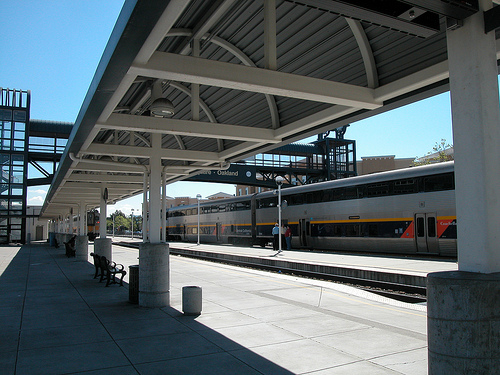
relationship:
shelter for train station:
[35, 0, 481, 227] [2, 2, 496, 370]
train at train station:
[142, 148, 469, 264] [2, 2, 496, 370]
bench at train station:
[86, 251, 135, 290] [2, 2, 496, 370]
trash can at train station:
[124, 261, 146, 306] [2, 2, 496, 370]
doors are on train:
[410, 208, 439, 257] [142, 148, 469, 264]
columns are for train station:
[50, 97, 177, 319] [2, 2, 496, 370]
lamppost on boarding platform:
[269, 168, 293, 259] [78, 233, 438, 355]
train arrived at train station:
[142, 148, 469, 264] [2, 2, 496, 370]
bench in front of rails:
[86, 251, 135, 290] [119, 236, 428, 313]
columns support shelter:
[50, 97, 177, 319] [35, 0, 481, 227]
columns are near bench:
[50, 97, 177, 319] [86, 251, 135, 290]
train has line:
[142, 148, 469, 264] [309, 214, 414, 230]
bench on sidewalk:
[86, 251, 135, 290] [14, 240, 209, 368]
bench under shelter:
[86, 251, 135, 290] [35, 0, 481, 227]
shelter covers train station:
[35, 0, 481, 227] [2, 2, 496, 370]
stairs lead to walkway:
[0, 123, 32, 253] [0, 79, 374, 200]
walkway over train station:
[0, 79, 374, 200] [2, 2, 496, 370]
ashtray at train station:
[176, 284, 205, 293] [2, 2, 496, 370]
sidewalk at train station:
[14, 240, 209, 368] [2, 2, 496, 370]